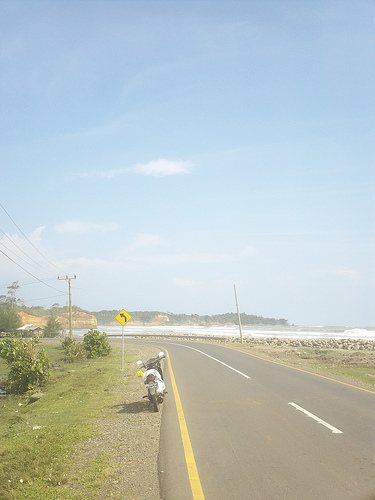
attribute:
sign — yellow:
[110, 307, 131, 370]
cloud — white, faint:
[109, 148, 196, 196]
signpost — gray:
[113, 308, 132, 371]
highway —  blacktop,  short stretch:
[163, 341, 373, 498]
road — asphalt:
[31, 338, 351, 491]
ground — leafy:
[281, 118, 299, 138]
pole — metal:
[120, 323, 128, 376]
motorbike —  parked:
[135, 349, 169, 412]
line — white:
[286, 400, 344, 434]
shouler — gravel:
[79, 346, 162, 498]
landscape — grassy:
[3, 308, 374, 498]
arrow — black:
[108, 311, 148, 343]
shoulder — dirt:
[66, 336, 166, 497]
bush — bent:
[0, 334, 49, 397]